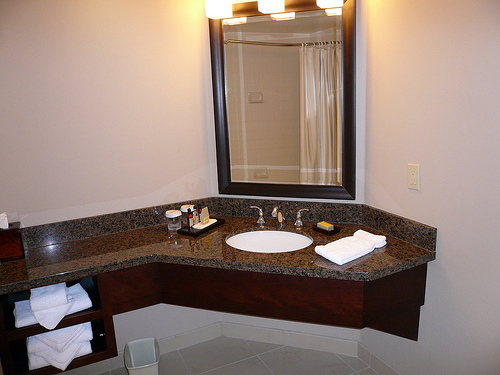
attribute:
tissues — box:
[3, 194, 35, 267]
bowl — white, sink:
[215, 219, 316, 260]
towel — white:
[317, 219, 392, 270]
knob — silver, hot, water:
[248, 200, 265, 223]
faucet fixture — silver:
[252, 205, 264, 224]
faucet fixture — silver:
[268, 201, 283, 226]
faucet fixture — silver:
[293, 207, 308, 229]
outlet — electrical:
[390, 161, 435, 196]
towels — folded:
[13, 281, 92, 371]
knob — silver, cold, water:
[295, 207, 306, 227]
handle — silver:
[288, 209, 310, 235]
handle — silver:
[247, 203, 272, 233]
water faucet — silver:
[266, 199, 288, 229]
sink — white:
[223, 228, 313, 257]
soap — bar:
[316, 220, 333, 232]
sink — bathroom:
[225, 228, 316, 253]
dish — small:
[312, 225, 342, 232]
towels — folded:
[29, 278, 78, 332]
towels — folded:
[25, 323, 96, 371]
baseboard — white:
[84, 311, 392, 372]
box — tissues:
[3, 214, 35, 269]